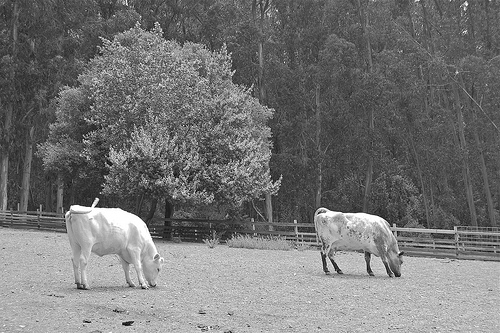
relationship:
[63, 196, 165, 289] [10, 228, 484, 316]
cow eating grass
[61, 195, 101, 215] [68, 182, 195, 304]
tail of cow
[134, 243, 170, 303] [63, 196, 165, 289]
head of cow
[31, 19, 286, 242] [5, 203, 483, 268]
tree outside fence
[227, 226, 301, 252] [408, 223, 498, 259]
grass inside fence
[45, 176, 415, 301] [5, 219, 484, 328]
cows in field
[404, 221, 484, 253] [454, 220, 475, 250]
fence with post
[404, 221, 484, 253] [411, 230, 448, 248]
fence with slats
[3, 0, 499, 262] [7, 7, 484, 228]
forest of trees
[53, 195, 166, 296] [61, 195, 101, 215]
pig with tail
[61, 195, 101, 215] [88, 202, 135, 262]
tail curled over body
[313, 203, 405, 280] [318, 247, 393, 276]
pig with legs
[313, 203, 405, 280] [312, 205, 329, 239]
pig with tail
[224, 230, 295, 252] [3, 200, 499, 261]
plants growing near fence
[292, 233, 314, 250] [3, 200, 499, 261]
plants growing near fence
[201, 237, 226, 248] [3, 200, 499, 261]
plants growing near fence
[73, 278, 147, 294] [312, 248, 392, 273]
shadow between legs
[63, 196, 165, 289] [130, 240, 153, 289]
cow has leg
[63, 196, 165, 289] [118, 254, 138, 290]
cow has leg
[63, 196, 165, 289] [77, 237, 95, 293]
cow has leg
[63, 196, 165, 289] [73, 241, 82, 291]
cow has leg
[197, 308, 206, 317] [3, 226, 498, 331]
rock in field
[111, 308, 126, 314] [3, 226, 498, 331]
rock in field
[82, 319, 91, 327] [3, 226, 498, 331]
rock in field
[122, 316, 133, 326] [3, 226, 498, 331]
rock in field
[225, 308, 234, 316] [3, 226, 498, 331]
rock in field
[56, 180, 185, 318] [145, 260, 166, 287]
cow has face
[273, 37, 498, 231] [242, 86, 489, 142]
forest on background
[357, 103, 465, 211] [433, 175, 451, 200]
forest has part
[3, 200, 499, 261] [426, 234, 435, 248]
fence has part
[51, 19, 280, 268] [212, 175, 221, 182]
tree has edge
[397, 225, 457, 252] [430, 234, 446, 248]
fence has part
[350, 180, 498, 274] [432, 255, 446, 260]
fence has edge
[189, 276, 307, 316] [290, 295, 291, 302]
surface has part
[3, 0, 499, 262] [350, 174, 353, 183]
forest has part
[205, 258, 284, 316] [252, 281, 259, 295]
ground has part